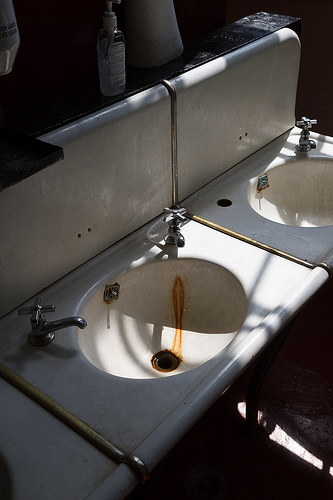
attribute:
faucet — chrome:
[16, 298, 88, 344]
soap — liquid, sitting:
[95, 0, 129, 101]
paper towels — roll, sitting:
[113, 1, 191, 69]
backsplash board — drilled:
[0, 146, 175, 302]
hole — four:
[86, 226, 93, 233]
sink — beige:
[229, 150, 331, 244]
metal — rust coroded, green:
[255, 175, 271, 191]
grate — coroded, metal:
[104, 284, 122, 299]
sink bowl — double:
[61, 256, 256, 366]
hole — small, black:
[215, 196, 233, 208]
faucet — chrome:
[159, 205, 193, 249]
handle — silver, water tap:
[288, 110, 314, 149]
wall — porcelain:
[21, 136, 171, 273]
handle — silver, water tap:
[160, 204, 187, 247]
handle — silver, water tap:
[18, 297, 87, 347]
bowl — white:
[76, 256, 247, 378]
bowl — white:
[248, 159, 332, 227]